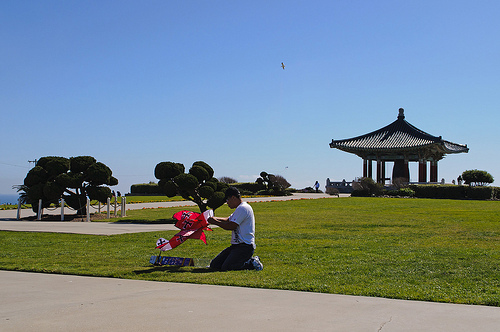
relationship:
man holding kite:
[206, 186, 265, 272] [153, 208, 215, 252]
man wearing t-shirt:
[206, 186, 265, 272] [227, 203, 257, 246]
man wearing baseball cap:
[206, 186, 265, 272] [219, 186, 241, 205]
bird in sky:
[279, 60, 287, 70] [1, 0, 499, 201]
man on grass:
[206, 186, 265, 272] [0, 199, 498, 305]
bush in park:
[21, 154, 118, 218] [0, 106, 499, 330]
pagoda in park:
[326, 106, 470, 194] [0, 106, 499, 330]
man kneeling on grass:
[206, 186, 265, 272] [0, 199, 498, 305]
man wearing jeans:
[206, 186, 265, 272] [207, 242, 254, 271]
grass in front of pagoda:
[0, 199, 498, 305] [326, 106, 470, 194]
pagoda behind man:
[326, 106, 470, 194] [206, 186, 265, 272]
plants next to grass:
[247, 195, 332, 204] [0, 199, 498, 305]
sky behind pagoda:
[1, 0, 499, 201] [326, 106, 470, 194]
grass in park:
[0, 199, 498, 305] [0, 106, 499, 330]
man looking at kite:
[206, 186, 265, 272] [153, 208, 215, 252]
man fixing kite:
[206, 186, 265, 272] [153, 208, 215, 252]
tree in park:
[153, 160, 229, 211] [0, 106, 499, 330]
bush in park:
[408, 182, 492, 201] [0, 106, 499, 330]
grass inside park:
[0, 199, 498, 305] [0, 106, 499, 330]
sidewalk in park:
[0, 266, 499, 331] [0, 106, 499, 330]